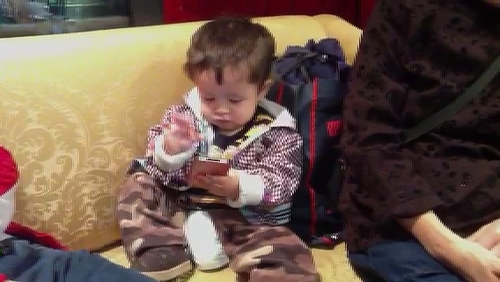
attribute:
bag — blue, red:
[280, 40, 349, 251]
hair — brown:
[175, 15, 282, 83]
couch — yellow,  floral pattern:
[3, 8, 377, 280]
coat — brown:
[127, 85, 303, 225]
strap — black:
[386, 58, 498, 156]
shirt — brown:
[341, 0, 496, 255]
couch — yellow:
[4, 28, 150, 250]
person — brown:
[333, 4, 498, 280]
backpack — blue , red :
[274, 37, 354, 247]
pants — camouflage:
[116, 166, 322, 280]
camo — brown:
[98, 183, 192, 280]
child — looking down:
[108, 12, 324, 280]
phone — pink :
[188, 152, 230, 194]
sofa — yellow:
[7, 32, 422, 214]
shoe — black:
[130, 243, 191, 280]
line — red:
[309, 78, 318, 226]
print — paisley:
[6, 42, 129, 252]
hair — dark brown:
[184, 16, 274, 93]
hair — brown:
[178, 10, 287, 97]